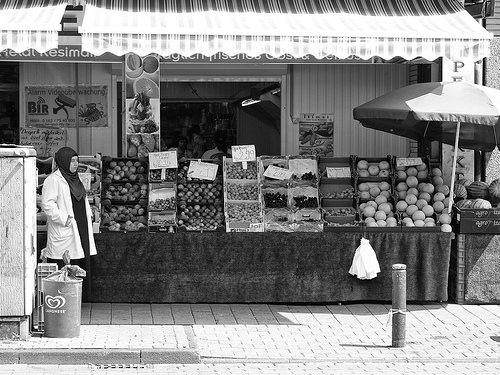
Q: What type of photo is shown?
A: Black and white.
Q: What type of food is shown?
A: Fruits.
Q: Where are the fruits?
A: Shelf.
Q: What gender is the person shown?
A: Female.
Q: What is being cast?
A: Shadows.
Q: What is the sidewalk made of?
A: Wooden boards.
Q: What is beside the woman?
A: Trash can.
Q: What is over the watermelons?
A: Umbrella.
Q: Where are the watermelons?
A: Right side of the image.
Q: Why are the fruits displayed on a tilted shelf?
A: For customers to view them.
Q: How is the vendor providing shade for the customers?
A: An awning over the sidewalk.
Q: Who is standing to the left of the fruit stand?
A: A woman wearing a head scarf.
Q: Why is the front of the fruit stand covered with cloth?
A: To cover storage area.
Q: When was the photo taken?
A: Daytime.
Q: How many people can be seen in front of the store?
A: One.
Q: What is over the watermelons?
A: Umbrella.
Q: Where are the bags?
A: Hanging.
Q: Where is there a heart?
A: Trash can.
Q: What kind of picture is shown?
A: Black and white.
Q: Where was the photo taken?
A: Fruit stand.